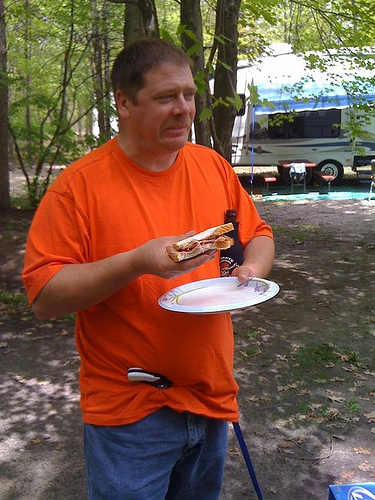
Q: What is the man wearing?
A: Shirt.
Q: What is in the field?
A: Trees.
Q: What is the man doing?
A: Eating outside.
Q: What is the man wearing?
A: Blue jeans.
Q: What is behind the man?
A: Dirt on the ground.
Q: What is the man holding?
A: A sandwich.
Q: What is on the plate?
A: A sandwich.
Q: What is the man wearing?
A: An orange t-shirt.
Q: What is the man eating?
A: Sandwich.